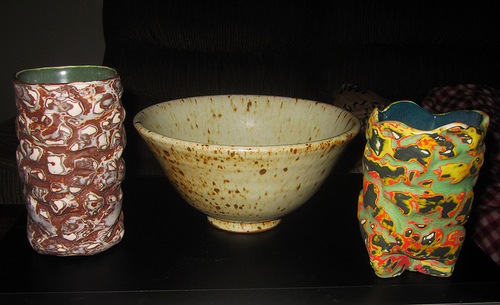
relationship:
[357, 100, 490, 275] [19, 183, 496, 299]
pot rests on table